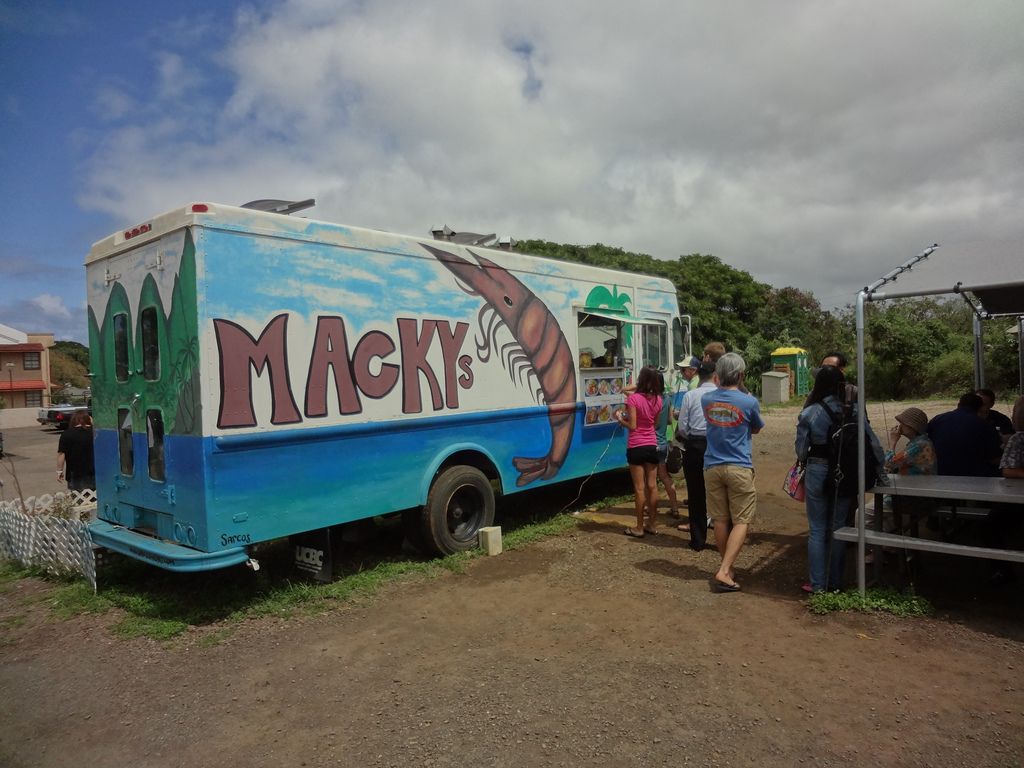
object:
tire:
[667, 446, 685, 479]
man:
[700, 352, 765, 590]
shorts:
[703, 465, 757, 523]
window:
[146, 409, 165, 484]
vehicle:
[82, 198, 693, 584]